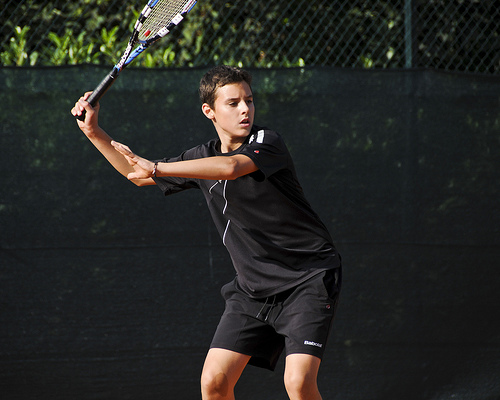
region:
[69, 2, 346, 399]
Boy swinging tennis racket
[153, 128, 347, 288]
Black shirt with white design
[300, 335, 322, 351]
White logo on black shorts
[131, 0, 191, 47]
Strings on tennis racket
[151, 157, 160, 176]
Bracelet on boy's wrist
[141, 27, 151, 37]
Red sticker on strings of tennis racket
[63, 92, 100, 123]
Handle of tennis racket in boy's hand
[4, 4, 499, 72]
Chain link fence around tennis court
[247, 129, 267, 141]
White stripe on shoulder of black shirt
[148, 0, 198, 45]
Black and white stripes on tennis racket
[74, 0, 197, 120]
the racquet in the boy's hand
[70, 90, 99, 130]
the hand holding the racquet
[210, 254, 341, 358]
the shorts on the boy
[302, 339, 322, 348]
the white letters on the shorts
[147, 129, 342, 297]
the short sleeved shirt on the boy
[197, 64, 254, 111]
the hair on the boy's head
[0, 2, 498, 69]
the chain link fence above the fabric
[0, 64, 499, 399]
the fabric on the chain link fence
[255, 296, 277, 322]
the string on the shorts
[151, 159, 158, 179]
the item on the boy's hand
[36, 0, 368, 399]
boy is playing tennis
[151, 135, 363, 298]
boy's shirt is black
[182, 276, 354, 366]
boy's shorts are black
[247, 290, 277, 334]
draw string on shorts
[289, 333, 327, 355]
white letters on shorts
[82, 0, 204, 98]
tennis racket is blue white and black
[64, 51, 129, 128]
racket's handle is black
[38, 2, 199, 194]
racket in boy's right hand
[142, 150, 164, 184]
boy wearing a bracelet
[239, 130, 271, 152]
white stripes on shirt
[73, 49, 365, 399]
a young man in black playing tennis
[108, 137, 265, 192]
the arm of a young man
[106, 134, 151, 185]
the hand of a person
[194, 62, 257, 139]
the head of a young man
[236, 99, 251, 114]
the nose of a young man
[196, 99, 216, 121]
the ear of a person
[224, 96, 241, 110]
the eye of a person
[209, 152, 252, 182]
the elbow of an arm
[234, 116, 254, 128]
the mouth of a person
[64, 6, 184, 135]
a hand holding a tennis racket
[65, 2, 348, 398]
A boy playing tennis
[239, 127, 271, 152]
Two white stripes on shirt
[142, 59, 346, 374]
Player is wearing a black outfit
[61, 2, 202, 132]
Tennis racket in a hand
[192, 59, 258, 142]
Brown hair on boy's head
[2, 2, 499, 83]
Green fence behind the player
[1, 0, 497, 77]
Green trees behind the fence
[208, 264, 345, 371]
A pair of black shorts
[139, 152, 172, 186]
A bracelet around a wrist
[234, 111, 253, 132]
A mouth is open